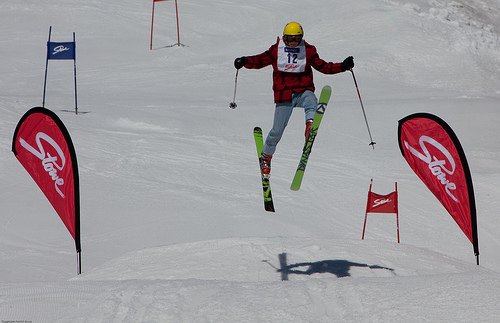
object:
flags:
[10, 106, 82, 252]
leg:
[260, 105, 292, 156]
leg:
[297, 91, 319, 123]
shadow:
[259, 252, 397, 282]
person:
[232, 20, 355, 175]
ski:
[250, 126, 277, 211]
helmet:
[281, 20, 306, 45]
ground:
[0, 0, 499, 323]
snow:
[0, 0, 499, 323]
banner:
[11, 105, 82, 253]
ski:
[287, 85, 332, 192]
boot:
[257, 151, 274, 176]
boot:
[301, 118, 316, 147]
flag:
[394, 111, 480, 256]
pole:
[228, 70, 243, 109]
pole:
[349, 68, 376, 150]